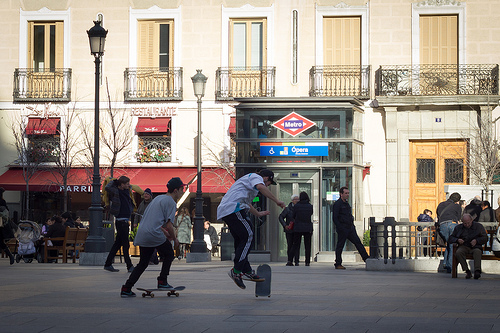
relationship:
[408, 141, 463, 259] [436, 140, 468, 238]
door has window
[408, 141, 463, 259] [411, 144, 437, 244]
door has window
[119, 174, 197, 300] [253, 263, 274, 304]
boy riding skateboard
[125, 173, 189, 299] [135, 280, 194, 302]
boy riding skate board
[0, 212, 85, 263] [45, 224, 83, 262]
people sitting on bench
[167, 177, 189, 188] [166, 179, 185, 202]
hat on head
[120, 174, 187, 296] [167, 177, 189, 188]
boy has hat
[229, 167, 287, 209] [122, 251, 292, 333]
skateboarder performing a trick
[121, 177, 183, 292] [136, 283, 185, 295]
man running on h skateboard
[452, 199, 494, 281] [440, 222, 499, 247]
man sitting on a bench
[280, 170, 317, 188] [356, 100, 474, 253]
door on front of a building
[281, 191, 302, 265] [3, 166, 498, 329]
person standing in public place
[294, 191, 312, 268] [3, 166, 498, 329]
person standing in public place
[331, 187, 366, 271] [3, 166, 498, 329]
person standing in public place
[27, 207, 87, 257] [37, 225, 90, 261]
people sitting on bench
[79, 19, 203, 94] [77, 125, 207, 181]
lights on poles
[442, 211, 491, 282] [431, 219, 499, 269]
man sitting on bench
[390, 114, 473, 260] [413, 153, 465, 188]
doors with windows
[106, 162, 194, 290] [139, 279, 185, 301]
man on skateboard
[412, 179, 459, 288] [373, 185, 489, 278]
man on bench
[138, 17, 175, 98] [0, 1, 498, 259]
window on building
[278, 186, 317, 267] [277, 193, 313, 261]
people talking people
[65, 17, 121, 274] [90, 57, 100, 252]
street lamp on pole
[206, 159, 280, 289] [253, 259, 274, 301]
man doing trick on skateboard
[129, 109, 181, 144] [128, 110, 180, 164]
red awning above window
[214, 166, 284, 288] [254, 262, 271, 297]
skateboarder flipping skateboard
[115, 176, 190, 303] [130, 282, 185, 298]
skateboarder riding skateboard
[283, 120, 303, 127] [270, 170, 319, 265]
metro sign at entrance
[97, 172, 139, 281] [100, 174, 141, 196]
man carrying something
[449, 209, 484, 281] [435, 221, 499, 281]
man on bench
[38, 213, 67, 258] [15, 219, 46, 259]
woman next to carriage